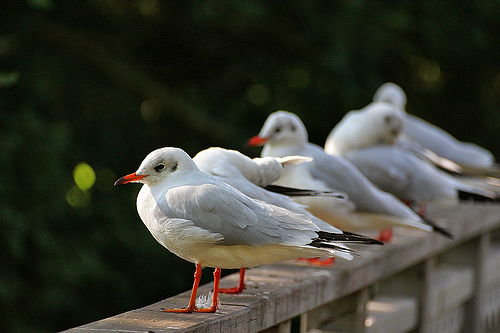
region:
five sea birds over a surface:
[104, 75, 491, 318]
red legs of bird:
[172, 262, 227, 319]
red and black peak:
[112, 169, 144, 190]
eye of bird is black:
[149, 155, 172, 177]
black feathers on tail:
[283, 217, 380, 269]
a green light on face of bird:
[58, 137, 185, 247]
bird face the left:
[99, 138, 206, 238]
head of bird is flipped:
[323, 90, 408, 175]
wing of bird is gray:
[158, 175, 298, 246]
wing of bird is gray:
[305, 145, 395, 216]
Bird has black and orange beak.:
[116, 168, 136, 187]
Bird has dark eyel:
[153, 156, 164, 179]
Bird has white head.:
[144, 138, 190, 175]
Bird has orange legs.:
[173, 265, 240, 301]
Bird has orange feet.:
[146, 293, 220, 331]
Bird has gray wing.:
[195, 200, 277, 240]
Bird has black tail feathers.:
[313, 228, 365, 272]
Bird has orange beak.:
[235, 128, 269, 163]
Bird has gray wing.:
[326, 158, 373, 211]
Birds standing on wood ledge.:
[168, 149, 488, 273]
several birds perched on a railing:
[111, 65, 489, 306]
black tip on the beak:
[111, 174, 125, 187]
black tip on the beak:
[243, 136, 251, 146]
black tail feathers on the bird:
[315, 222, 365, 238]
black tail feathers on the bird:
[418, 211, 453, 241]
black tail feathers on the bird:
[459, 185, 489, 207]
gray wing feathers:
[187, 182, 283, 236]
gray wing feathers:
[320, 157, 352, 182]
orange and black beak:
[110, 170, 151, 188]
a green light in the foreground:
[71, 159, 93, 199]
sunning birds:
[107, 141, 364, 318]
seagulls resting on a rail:
[111, 85, 493, 315]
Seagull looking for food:
[106, 135, 376, 315]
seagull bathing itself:
[196, 140, 362, 222]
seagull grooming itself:
[324, 96, 479, 198]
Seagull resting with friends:
[110, 143, 384, 323]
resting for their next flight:
[108, 100, 482, 305]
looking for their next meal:
[106, 140, 388, 329]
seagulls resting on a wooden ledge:
[107, 106, 460, 312]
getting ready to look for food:
[110, 135, 385, 323]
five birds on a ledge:
[58, 57, 498, 278]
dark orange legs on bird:
[155, 243, 244, 325]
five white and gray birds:
[69, 76, 491, 291]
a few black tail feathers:
[302, 217, 399, 271]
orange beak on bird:
[116, 170, 146, 195]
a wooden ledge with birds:
[95, 193, 499, 331]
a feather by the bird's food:
[185, 281, 235, 315]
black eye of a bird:
[155, 162, 172, 177]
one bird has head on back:
[332, 80, 419, 167]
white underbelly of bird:
[187, 244, 287, 269]